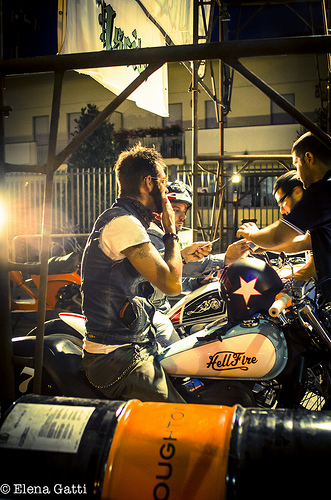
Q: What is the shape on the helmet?
A: A star.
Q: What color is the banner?
A: White.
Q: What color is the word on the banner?
A: Green.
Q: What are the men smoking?
A: Cigarettes.